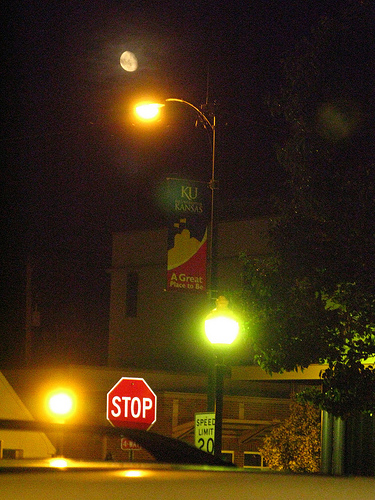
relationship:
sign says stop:
[104, 374, 159, 432] [113, 396, 152, 419]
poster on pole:
[161, 177, 211, 293] [130, 92, 221, 307]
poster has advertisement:
[161, 177, 211, 293] [171, 219, 208, 290]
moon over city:
[118, 45, 146, 75] [2, 85, 374, 498]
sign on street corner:
[104, 374, 159, 432] [2, 353, 80, 499]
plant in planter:
[309, 361, 374, 411] [317, 391, 371, 478]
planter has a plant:
[317, 391, 371, 478] [309, 361, 374, 411]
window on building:
[123, 267, 142, 323] [103, 220, 287, 372]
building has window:
[103, 220, 287, 372] [123, 267, 142, 323]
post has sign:
[130, 92, 221, 307] [161, 177, 211, 293]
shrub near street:
[264, 390, 321, 468] [2, 396, 374, 493]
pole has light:
[130, 92, 221, 307] [122, 93, 173, 133]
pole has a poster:
[130, 92, 221, 307] [161, 177, 211, 293]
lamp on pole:
[196, 294, 246, 456] [212, 361, 226, 456]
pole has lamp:
[130, 92, 221, 307] [122, 93, 173, 133]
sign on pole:
[104, 374, 159, 432] [120, 442, 139, 460]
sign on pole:
[196, 415, 215, 454] [212, 361, 226, 456]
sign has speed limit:
[196, 415, 215, 454] [198, 436, 213, 452]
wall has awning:
[116, 388, 291, 469] [237, 362, 374, 384]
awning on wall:
[237, 362, 374, 384] [116, 388, 291, 469]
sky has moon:
[8, 9, 375, 304] [118, 45, 146, 75]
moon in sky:
[118, 45, 146, 75] [8, 9, 375, 304]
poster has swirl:
[161, 177, 211, 293] [158, 237, 210, 290]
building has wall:
[103, 220, 287, 372] [116, 266, 250, 370]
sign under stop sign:
[121, 436, 140, 452] [104, 374, 159, 432]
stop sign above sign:
[104, 374, 159, 432] [121, 436, 140, 452]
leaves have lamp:
[235, 268, 278, 370] [196, 294, 247, 356]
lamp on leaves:
[196, 294, 247, 356] [235, 268, 278, 370]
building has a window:
[103, 220, 287, 372] [123, 267, 142, 323]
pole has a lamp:
[212, 361, 226, 456] [196, 294, 247, 356]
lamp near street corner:
[196, 294, 246, 456] [2, 353, 80, 499]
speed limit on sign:
[198, 436, 213, 452] [196, 415, 215, 454]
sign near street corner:
[104, 374, 159, 432] [2, 353, 80, 499]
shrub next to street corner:
[264, 390, 321, 468] [2, 353, 80, 499]